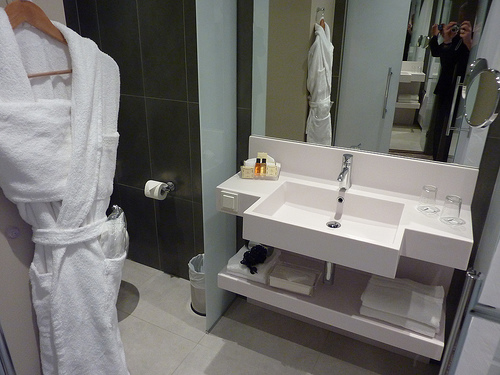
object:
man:
[422, 2, 478, 162]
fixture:
[336, 154, 353, 194]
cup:
[439, 195, 464, 227]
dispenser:
[166, 181, 176, 192]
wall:
[63, 0, 205, 282]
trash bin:
[186, 253, 209, 316]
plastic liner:
[184, 250, 207, 290]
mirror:
[464, 69, 500, 128]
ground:
[117, 256, 444, 374]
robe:
[6, 29, 179, 366]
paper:
[144, 180, 169, 201]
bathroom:
[0, 2, 499, 375]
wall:
[252, 58, 269, 137]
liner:
[187, 253, 206, 290]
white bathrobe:
[0, 7, 131, 375]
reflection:
[425, 17, 478, 75]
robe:
[1, 77, 121, 372]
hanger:
[4, 0, 67, 45]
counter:
[216, 168, 477, 251]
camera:
[450, 23, 461, 33]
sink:
[251, 181, 406, 246]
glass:
[417, 184, 438, 214]